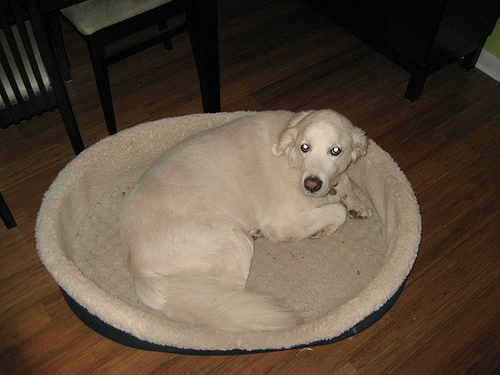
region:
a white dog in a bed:
[112, 91, 405, 327]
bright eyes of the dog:
[293, 137, 362, 168]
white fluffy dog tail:
[129, 243, 329, 365]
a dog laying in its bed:
[31, 70, 423, 371]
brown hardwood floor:
[440, 235, 481, 347]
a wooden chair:
[0, 1, 130, 213]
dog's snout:
[287, 157, 345, 216]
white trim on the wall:
[439, 49, 498, 81]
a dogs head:
[265, 92, 380, 205]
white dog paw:
[335, 180, 384, 227]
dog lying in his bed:
[5, 89, 424, 374]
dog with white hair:
[110, 104, 372, 336]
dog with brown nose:
[106, 93, 372, 364]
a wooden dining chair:
[0, 1, 112, 233]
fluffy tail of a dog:
[135, 271, 307, 347]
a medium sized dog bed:
[19, 98, 408, 360]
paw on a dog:
[339, 190, 379, 224]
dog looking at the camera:
[109, 96, 379, 343]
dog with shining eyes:
[101, 98, 387, 340]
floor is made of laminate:
[0, 35, 495, 374]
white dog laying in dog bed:
[34, 106, 422, 359]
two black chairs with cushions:
[0, 0, 222, 231]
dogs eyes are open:
[299, 141, 343, 157]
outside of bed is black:
[59, 276, 411, 357]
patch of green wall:
[480, 19, 498, 61]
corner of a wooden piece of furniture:
[307, 0, 497, 100]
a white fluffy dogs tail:
[144, 276, 299, 331]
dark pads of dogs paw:
[349, 207, 367, 222]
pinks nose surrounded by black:
[301, 174, 324, 196]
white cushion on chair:
[59, 0, 172, 40]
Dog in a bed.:
[123, 106, 379, 277]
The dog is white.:
[200, 169, 246, 199]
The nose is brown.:
[289, 175, 336, 201]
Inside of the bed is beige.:
[280, 262, 336, 289]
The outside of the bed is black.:
[74, 313, 138, 357]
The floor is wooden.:
[437, 316, 487, 365]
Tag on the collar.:
[318, 184, 348, 206]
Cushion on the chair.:
[73, 4, 126, 35]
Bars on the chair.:
[0, 31, 60, 76]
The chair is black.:
[95, 48, 127, 78]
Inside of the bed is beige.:
[53, 190, 121, 270]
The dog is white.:
[121, 109, 364, 291]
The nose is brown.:
[302, 168, 335, 190]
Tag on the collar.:
[314, 180, 350, 207]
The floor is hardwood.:
[426, 262, 498, 360]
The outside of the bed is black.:
[61, 301, 146, 348]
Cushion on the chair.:
[62, 2, 154, 30]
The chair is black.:
[79, 36, 231, 102]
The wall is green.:
[483, 7, 499, 77]